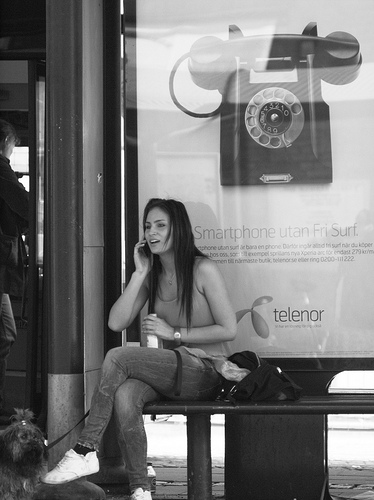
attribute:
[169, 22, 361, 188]
image — telephone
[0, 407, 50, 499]
dog — small, little, sitting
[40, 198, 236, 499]
woman — talking, sitting, young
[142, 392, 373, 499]
bench — metallic, black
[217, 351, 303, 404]
purse — black, opened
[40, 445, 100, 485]
sneaker — white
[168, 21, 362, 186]
telephone — vintage, black, large, house phone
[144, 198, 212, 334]
hair — down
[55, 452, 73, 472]
lace — white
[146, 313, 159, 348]
object — white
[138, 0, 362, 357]
billboard — outdoor, advertisement